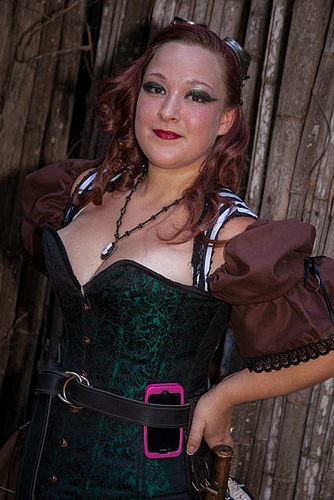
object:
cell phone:
[139, 380, 187, 465]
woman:
[0, 7, 334, 500]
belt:
[13, 354, 205, 499]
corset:
[20, 223, 235, 500]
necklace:
[125, 156, 203, 226]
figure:
[101, 240, 119, 261]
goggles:
[166, 8, 252, 84]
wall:
[0, 2, 333, 392]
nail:
[187, 444, 196, 456]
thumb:
[186, 416, 207, 457]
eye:
[183, 88, 217, 106]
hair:
[90, 13, 253, 249]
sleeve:
[203, 208, 334, 381]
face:
[132, 40, 227, 168]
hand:
[185, 383, 240, 464]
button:
[81, 302, 90, 314]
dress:
[0, 158, 333, 500]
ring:
[57, 370, 83, 406]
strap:
[188, 178, 261, 295]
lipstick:
[151, 127, 186, 142]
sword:
[187, 437, 235, 497]